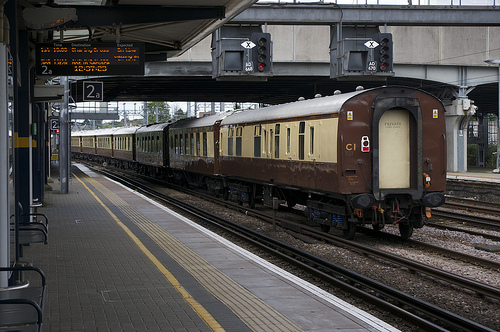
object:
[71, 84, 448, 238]
train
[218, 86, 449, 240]
car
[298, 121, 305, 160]
window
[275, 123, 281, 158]
window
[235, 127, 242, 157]
window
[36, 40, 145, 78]
sign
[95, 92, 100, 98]
letter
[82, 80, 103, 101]
sign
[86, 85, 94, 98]
number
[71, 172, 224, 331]
line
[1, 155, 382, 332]
platform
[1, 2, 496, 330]
station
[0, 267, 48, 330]
bench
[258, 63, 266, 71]
light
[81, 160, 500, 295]
tracks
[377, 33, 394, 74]
light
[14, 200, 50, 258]
bench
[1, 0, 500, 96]
overpass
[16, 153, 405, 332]
tracks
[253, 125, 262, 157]
window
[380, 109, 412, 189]
door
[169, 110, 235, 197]
car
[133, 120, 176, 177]
car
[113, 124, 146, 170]
car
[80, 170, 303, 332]
lines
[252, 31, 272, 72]
signal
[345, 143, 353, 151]
letter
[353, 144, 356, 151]
letter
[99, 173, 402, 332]
line